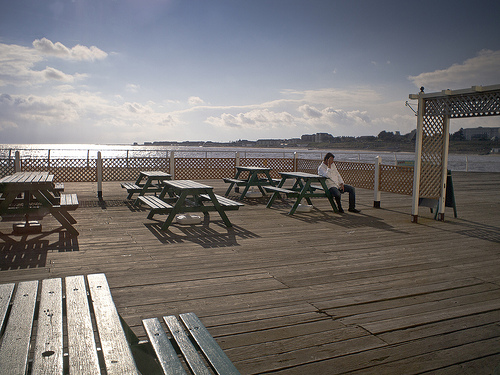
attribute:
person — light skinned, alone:
[317, 151, 362, 217]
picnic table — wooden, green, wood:
[265, 168, 345, 218]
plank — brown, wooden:
[323, 279, 498, 317]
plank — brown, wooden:
[310, 274, 483, 311]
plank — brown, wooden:
[326, 288, 497, 324]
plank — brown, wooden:
[349, 299, 497, 339]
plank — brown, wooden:
[373, 310, 500, 348]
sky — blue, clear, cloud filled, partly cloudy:
[2, 2, 497, 146]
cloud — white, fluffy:
[1, 37, 121, 84]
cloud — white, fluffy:
[203, 105, 306, 134]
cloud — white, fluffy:
[297, 103, 386, 131]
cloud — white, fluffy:
[410, 46, 499, 88]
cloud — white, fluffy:
[156, 113, 182, 130]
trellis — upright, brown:
[405, 78, 499, 219]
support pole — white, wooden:
[413, 99, 420, 220]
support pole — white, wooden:
[441, 101, 451, 217]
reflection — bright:
[23, 142, 150, 162]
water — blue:
[1, 141, 499, 169]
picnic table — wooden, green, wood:
[220, 160, 283, 207]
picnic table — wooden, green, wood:
[136, 178, 244, 239]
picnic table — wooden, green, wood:
[120, 168, 185, 212]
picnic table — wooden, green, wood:
[4, 171, 85, 234]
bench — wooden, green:
[313, 182, 344, 195]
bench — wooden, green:
[262, 184, 308, 204]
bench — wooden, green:
[224, 176, 244, 189]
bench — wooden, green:
[201, 190, 246, 214]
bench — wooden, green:
[138, 193, 177, 219]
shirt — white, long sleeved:
[318, 162, 351, 190]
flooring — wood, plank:
[6, 180, 498, 374]